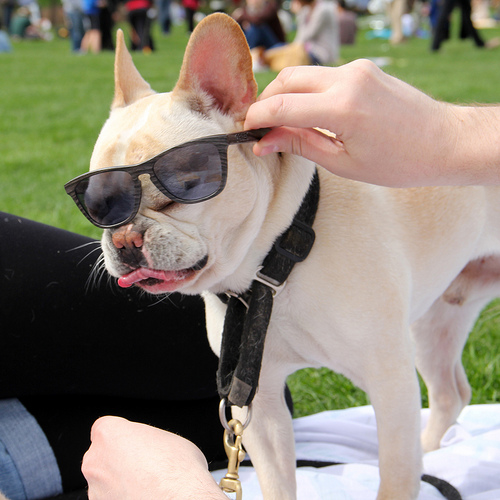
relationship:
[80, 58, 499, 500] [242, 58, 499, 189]
person has a right hand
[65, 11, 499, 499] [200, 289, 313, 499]
dog has a front right leg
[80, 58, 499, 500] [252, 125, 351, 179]
person has a thumb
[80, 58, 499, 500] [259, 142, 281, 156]
person has a thumbnail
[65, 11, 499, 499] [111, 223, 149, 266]
dog has a nose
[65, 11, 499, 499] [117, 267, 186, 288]
dog has a tongue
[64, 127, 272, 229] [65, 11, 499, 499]
sunglasses are being put on dog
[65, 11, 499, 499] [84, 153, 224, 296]
dog has a face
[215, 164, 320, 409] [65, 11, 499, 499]
dog collar on dog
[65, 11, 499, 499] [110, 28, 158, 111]
dog has a right ear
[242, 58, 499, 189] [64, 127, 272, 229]
right hand holding sunglasses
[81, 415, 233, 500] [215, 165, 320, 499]
left hand holding dog leash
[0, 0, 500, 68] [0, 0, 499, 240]
group of people are in background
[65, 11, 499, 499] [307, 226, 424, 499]
dog has a front left leg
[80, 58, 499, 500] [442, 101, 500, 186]
person has a wrist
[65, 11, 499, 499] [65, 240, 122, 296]
dog has a group of whiskers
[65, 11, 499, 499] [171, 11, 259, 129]
dog has a left ear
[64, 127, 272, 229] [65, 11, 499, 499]
sunglasses are on dog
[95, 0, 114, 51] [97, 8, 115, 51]
person has pants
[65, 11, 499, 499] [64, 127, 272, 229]
dog wearing sunglasses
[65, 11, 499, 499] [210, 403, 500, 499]
dog on top of a blanket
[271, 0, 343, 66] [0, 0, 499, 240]
person in background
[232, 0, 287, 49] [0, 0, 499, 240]
person in background